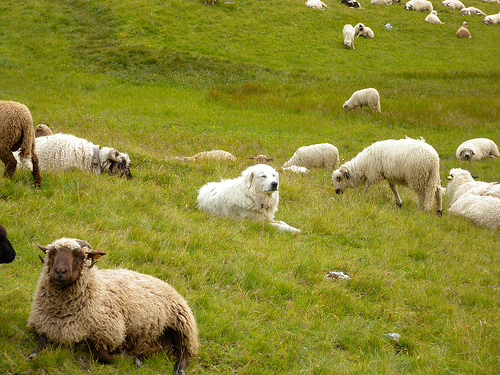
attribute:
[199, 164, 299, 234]
dog — laying 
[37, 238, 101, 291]
face — brown 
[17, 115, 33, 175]
tail — long, brown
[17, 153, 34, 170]
tip — cream colored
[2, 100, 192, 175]
field — green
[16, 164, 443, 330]
field — green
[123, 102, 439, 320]
field — green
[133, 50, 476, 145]
field — green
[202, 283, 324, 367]
field — green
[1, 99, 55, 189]
sheep — brown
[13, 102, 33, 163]
tail — long, brown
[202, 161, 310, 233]
dog — white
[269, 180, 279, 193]
nose — black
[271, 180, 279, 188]
nose — black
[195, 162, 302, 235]
dog — white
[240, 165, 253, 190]
right ear — white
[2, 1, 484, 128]
hill — brownest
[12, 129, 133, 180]
sheep — white, sleeping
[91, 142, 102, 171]
collar — gray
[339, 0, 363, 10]
sheep — blackest